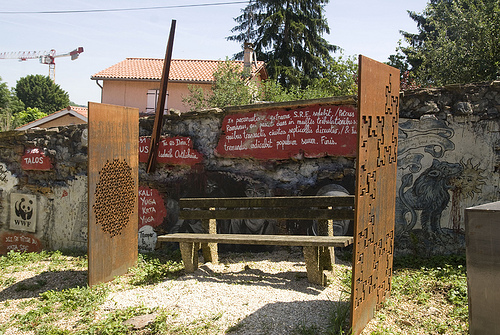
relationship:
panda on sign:
[11, 195, 36, 220] [1, 189, 53, 267]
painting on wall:
[399, 157, 453, 235] [406, 95, 459, 241]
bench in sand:
[179, 196, 326, 275] [191, 279, 249, 311]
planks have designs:
[335, 46, 417, 323] [352, 105, 401, 161]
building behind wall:
[103, 53, 219, 111] [406, 95, 459, 241]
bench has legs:
[179, 196, 326, 275] [174, 236, 208, 277]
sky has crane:
[23, 12, 68, 40] [30, 42, 89, 83]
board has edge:
[72, 93, 145, 243] [78, 138, 98, 166]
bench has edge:
[157, 196, 356, 286] [78, 138, 98, 166]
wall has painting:
[406, 95, 459, 241] [399, 157, 453, 235]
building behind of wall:
[103, 53, 219, 111] [406, 95, 459, 241]